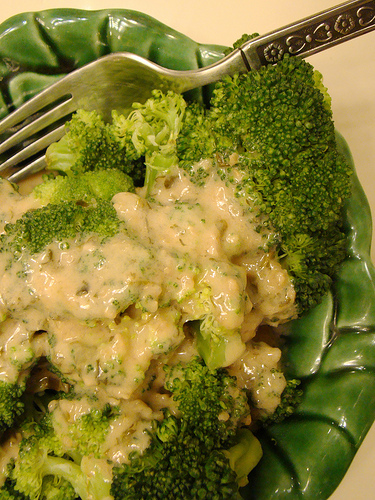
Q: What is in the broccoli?
A: A fork.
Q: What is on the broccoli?
A: Cheese sauce.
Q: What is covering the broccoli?
A: Cheese.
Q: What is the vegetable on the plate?
A: Broccoli.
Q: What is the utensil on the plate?
A: Fork.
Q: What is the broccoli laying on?
A: Plate.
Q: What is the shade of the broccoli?
A: Green.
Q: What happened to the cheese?
A: Melted.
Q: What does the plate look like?
A: Leaf.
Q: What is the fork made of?
A: Metal.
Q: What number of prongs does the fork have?
A: 4.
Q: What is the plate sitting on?
A: Table.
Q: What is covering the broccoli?
A: Cheese.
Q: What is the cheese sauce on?
A: Broccoli.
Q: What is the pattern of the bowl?
A: Leaf.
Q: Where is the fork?
A: On the plate.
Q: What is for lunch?
A: Broccoli and cheese sauce.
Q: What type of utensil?
A: Fork.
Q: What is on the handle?
A: Design.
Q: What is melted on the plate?
A: Cheese.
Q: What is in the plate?
A: Fork.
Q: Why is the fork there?
A: To eat.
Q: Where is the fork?
A: In the bowl.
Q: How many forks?
A: 1.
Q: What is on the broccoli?
A: Cheese.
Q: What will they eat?
A: Broccoli and cheese.